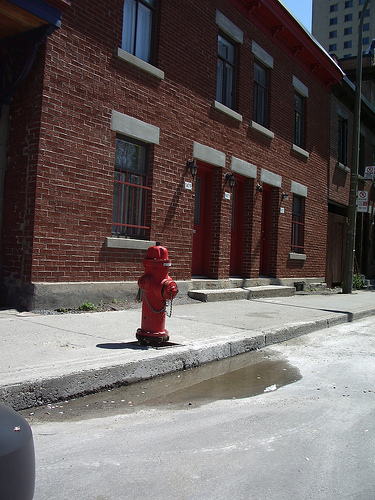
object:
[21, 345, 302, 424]
puddle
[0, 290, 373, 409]
sidewalk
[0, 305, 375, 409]
step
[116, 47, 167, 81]
sill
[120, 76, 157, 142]
window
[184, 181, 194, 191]
sign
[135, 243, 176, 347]
hydrant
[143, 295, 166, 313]
chain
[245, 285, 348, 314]
shadow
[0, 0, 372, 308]
residence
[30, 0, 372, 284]
wall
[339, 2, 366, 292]
pole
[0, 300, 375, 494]
street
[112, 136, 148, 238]
window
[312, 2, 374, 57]
building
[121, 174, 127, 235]
bars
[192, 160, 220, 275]
door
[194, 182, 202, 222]
window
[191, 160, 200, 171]
light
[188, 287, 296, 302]
steps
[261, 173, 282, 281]
doorways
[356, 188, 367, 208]
signs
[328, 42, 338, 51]
windows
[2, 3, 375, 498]
city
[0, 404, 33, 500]
car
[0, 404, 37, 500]
bumper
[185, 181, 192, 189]
numbers